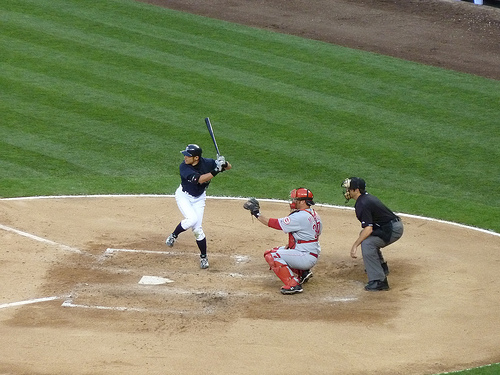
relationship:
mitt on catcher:
[244, 197, 260, 215] [245, 187, 322, 292]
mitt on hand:
[244, 197, 260, 215] [243, 193, 263, 217]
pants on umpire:
[359, 217, 405, 284] [340, 175, 402, 293]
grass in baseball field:
[14, 4, 496, 227] [0, 0, 500, 374]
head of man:
[179, 142, 206, 167] [164, 142, 231, 269]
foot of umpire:
[164, 233, 176, 248] [340, 175, 402, 293]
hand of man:
[214, 155, 226, 172] [166, 142, 231, 269]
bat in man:
[198, 102, 228, 169] [168, 125, 240, 268]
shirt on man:
[176, 157, 225, 197] [166, 142, 231, 269]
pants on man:
[173, 184, 206, 242] [166, 142, 231, 269]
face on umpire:
[346, 186, 359, 199] [340, 175, 402, 293]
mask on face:
[338, 178, 350, 202] [346, 186, 359, 199]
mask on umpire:
[338, 178, 350, 202] [340, 175, 402, 293]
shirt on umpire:
[164, 160, 236, 200] [340, 175, 402, 293]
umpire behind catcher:
[338, 175, 412, 296] [240, 188, 325, 295]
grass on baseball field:
[0, 0, 500, 233] [9, 2, 479, 372]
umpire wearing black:
[340, 175, 402, 293] [340, 177, 400, 227]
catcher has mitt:
[245, 187, 322, 292] [241, 195, 259, 215]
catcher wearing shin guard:
[245, 187, 322, 292] [262, 249, 295, 290]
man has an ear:
[164, 142, 231, 269] [196, 151, 204, 162]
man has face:
[166, 142, 231, 269] [185, 150, 199, 168]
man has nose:
[166, 142, 231, 269] [182, 155, 193, 165]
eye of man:
[187, 155, 193, 157] [168, 143, 220, 268]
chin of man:
[180, 160, 192, 165] [166, 142, 231, 269]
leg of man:
[163, 191, 198, 248] [166, 142, 231, 269]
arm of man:
[180, 167, 220, 183] [166, 142, 231, 269]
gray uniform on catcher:
[277, 207, 322, 267] [245, 187, 322, 292]